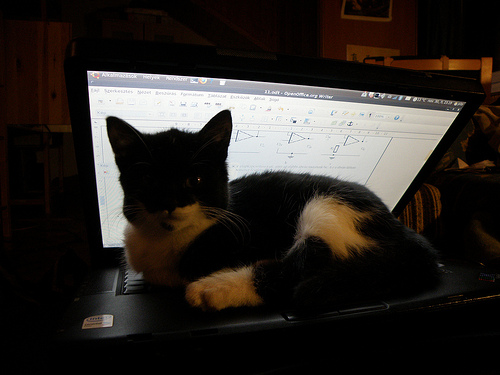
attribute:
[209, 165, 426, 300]
hair — long, black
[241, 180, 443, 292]
hair — long, black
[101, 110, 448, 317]
cat — white, black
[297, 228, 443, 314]
tail — cat, black, white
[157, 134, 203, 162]
hair — black, long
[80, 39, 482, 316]
laptop — pc, black, partially closed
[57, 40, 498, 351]
laptop — partially-closed, black, partially closed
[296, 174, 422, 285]
hair — long, black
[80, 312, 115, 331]
sticker — informational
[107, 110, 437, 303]
fur — long, black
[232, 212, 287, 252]
black hair — long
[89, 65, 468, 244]
program — computer's, software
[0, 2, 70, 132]
wood panels — varnished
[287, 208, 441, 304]
cat tail — white, black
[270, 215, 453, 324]
tail — black, white, cat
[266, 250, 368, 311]
tail — white, black, cat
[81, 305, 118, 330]
sticker — intel symbol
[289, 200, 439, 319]
cat tail — black, white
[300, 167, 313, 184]
hair — black, long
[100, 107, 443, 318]
animal — black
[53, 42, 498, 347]
computer — laptop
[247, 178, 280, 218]
hair — long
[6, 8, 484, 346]
room — darkened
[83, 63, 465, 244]
screen — lit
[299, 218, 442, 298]
tail — black, white, cat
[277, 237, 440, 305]
tail — white, black, cat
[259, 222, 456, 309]
tail — black, white